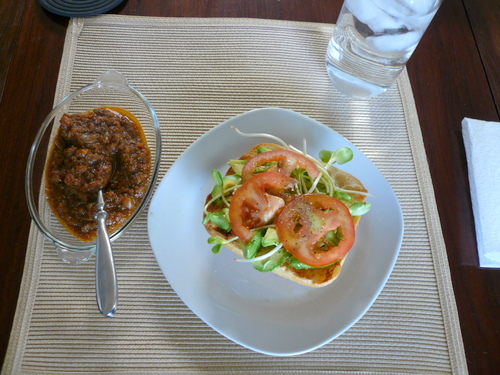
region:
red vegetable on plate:
[230, 146, 368, 270]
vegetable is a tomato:
[231, 152, 351, 259]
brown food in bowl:
[34, 101, 151, 225]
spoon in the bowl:
[78, 145, 132, 312]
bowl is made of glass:
[8, 42, 187, 265]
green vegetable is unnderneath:
[198, 142, 352, 270]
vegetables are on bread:
[203, 141, 362, 275]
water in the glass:
[338, 1, 418, 113]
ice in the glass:
[346, 0, 433, 50]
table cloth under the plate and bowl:
[41, 6, 454, 371]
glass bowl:
[21, 63, 164, 268]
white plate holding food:
[141, 106, 408, 361]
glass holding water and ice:
[321, 0, 440, 101]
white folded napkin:
[456, 114, 497, 277]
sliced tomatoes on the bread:
[224, 154, 361, 271]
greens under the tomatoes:
[201, 129, 377, 295]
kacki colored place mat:
[7, 15, 470, 373]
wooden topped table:
[429, 38, 495, 105]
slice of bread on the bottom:
[191, 129, 370, 286]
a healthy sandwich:
[202, 127, 391, 358]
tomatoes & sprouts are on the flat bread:
[236, 120, 379, 292]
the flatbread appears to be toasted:
[225, 144, 370, 287]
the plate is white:
[207, 136, 382, 352]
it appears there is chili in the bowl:
[51, 111, 152, 251]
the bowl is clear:
[18, 79, 175, 289]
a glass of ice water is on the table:
[311, 1, 443, 108]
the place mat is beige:
[81, 52, 424, 370]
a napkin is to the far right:
[463, 112, 498, 282]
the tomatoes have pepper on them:
[251, 148, 336, 270]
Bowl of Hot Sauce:
[22, 73, 162, 253]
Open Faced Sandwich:
[202, 138, 372, 284]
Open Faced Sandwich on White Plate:
[165, 103, 401, 352]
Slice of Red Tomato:
[279, 191, 356, 266]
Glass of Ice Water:
[335, 1, 424, 91]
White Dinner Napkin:
[473, 118, 495, 272]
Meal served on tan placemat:
[35, 6, 452, 353]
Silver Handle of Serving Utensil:
[91, 200, 121, 317]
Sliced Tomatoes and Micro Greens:
[235, 163, 344, 240]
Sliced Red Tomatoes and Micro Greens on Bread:
[206, 143, 371, 283]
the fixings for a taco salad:
[15, 13, 440, 356]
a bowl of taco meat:
[23, 66, 183, 311]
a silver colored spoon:
[64, 145, 140, 327]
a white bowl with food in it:
[141, 99, 414, 361]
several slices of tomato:
[241, 147, 355, 265]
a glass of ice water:
[326, 0, 433, 123]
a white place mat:
[38, 8, 466, 344]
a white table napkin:
[453, 109, 499, 285]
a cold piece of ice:
[365, 27, 420, 49]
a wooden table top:
[403, 0, 497, 371]